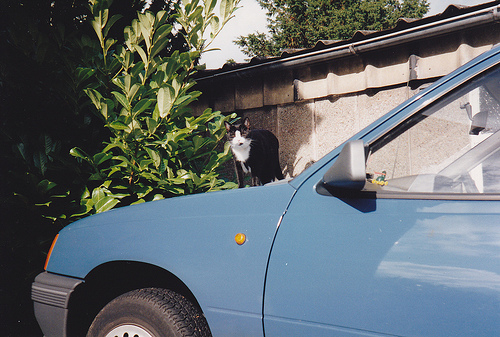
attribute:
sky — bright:
[136, 1, 499, 72]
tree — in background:
[233, 1, 433, 63]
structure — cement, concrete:
[182, 0, 500, 188]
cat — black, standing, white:
[224, 118, 288, 189]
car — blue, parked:
[30, 42, 499, 336]